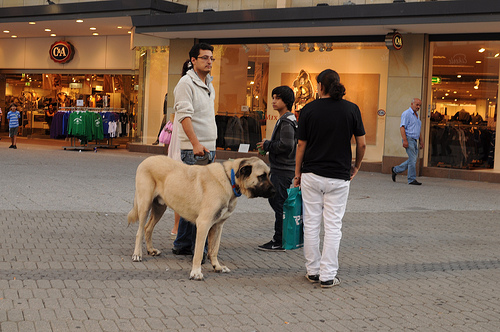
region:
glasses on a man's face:
[192, 51, 219, 64]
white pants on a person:
[296, 169, 349, 279]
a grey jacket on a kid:
[264, 109, 301, 169]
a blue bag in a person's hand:
[278, 178, 306, 255]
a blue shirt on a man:
[398, 103, 427, 137]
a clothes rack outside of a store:
[51, 104, 131, 155]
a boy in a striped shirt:
[3, 94, 26, 152]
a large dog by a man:
[124, 156, 277, 280]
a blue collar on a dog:
[225, 162, 241, 196]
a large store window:
[421, 38, 499, 169]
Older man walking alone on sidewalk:
[387, 96, 429, 188]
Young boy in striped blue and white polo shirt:
[5, 100, 22, 152]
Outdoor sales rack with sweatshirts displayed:
[46, 103, 129, 153]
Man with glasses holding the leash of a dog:
[171, 37, 218, 257]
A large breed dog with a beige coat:
[124, 151, 277, 279]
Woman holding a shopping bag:
[280, 68, 367, 288]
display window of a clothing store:
[422, 35, 498, 175]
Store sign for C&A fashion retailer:
[46, 37, 76, 65]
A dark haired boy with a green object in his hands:
[255, 82, 304, 252]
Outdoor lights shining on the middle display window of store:
[127, 42, 340, 54]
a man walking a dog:
[127, 38, 277, 280]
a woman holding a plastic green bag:
[283, 175, 304, 249]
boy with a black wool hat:
[271, 83, 297, 113]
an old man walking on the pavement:
[389, 95, 426, 186]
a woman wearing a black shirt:
[298, 97, 365, 184]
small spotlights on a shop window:
[239, 38, 336, 55]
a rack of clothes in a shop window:
[216, 109, 263, 149]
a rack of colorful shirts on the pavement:
[51, 105, 123, 141]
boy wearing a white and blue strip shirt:
[6, 110, 23, 129]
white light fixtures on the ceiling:
[3, 18, 135, 39]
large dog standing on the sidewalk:
[117, 146, 282, 292]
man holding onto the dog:
[122, 44, 281, 287]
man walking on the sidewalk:
[387, 95, 435, 188]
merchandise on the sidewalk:
[43, 102, 131, 153]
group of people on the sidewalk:
[132, 35, 372, 295]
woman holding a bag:
[282, 68, 367, 289]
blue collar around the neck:
[228, 166, 243, 195]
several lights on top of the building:
[0, 13, 129, 41]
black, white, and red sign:
[40, 38, 82, 66]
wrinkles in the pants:
[321, 195, 344, 239]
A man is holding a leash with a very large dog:
[129, 34, 279, 283]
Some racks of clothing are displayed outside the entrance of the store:
[52, 70, 137, 157]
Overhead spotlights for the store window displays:
[234, 42, 346, 63]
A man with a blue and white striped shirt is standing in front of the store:
[5, 100, 41, 151]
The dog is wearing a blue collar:
[214, 151, 281, 210]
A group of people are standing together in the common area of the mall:
[116, 26, 381, 297]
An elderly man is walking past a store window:
[378, 50, 456, 192]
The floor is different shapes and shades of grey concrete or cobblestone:
[0, 150, 132, 327]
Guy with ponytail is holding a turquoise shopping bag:
[281, 61, 371, 291]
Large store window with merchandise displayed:
[426, 42, 497, 172]